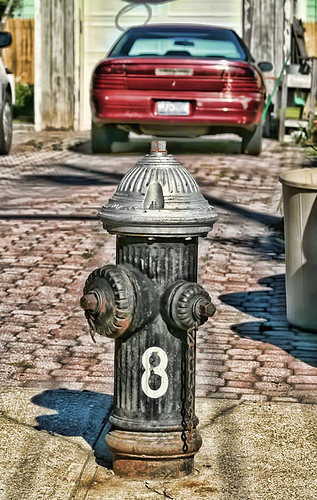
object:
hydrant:
[79, 141, 217, 480]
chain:
[187, 326, 197, 446]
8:
[140, 345, 169, 400]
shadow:
[29, 387, 113, 470]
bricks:
[14, 324, 54, 346]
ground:
[0, 130, 316, 403]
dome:
[97, 140, 219, 241]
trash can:
[277, 166, 317, 334]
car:
[89, 22, 274, 157]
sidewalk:
[0, 386, 316, 500]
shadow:
[179, 338, 188, 454]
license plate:
[155, 101, 190, 117]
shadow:
[114, 0, 152, 34]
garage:
[32, 0, 291, 141]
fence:
[0, 20, 316, 85]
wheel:
[242, 122, 262, 156]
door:
[80, 1, 243, 142]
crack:
[0, 399, 252, 499]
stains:
[0, 439, 6, 453]